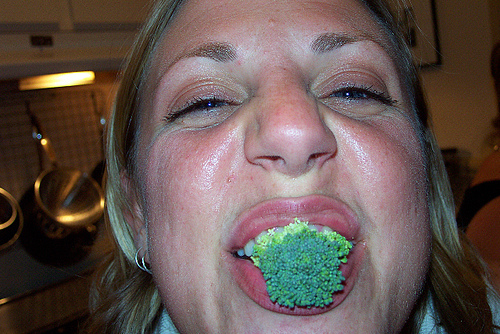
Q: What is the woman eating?
A: Broccoli.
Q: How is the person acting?
A: Happy.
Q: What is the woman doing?
A: Eating broccoli.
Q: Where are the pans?
A: Behind the woman.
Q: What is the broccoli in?
A: The woman's mouth.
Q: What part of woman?
A: Lips.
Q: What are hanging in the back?
A: Pots.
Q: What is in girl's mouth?
A: Broccoli.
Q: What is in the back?
A: Pan.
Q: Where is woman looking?
A: Camera.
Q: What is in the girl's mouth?
A: Broccoli.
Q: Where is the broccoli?
A: In the girl's mouth.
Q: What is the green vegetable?
A: Broccoli.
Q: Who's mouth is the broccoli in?
A: The girl's.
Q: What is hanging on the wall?
A: Pots and pans.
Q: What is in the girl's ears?
A: 2 earrings.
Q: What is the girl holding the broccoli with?
A: Her mouth.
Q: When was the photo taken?
A: Night time.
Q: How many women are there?
A: One.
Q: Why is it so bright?
A: The lamp.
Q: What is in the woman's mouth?
A: Broccoli.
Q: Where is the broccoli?
A: Womans mouth.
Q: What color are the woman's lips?
A: Pink.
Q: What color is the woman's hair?
A: Blonde.